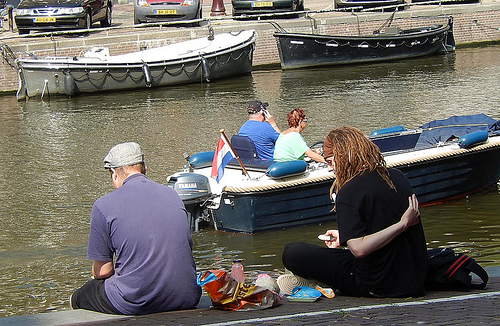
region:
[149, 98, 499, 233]
blue boat floating in the water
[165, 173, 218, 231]
outboard motor attached to boat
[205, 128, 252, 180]
flag hanging from flag pole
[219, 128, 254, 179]
flag pole attached to boat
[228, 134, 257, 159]
person leaning on blue backrest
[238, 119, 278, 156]
person wearing a bue shirt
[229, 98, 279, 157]
person is talking on the phone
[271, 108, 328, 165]
woman sitting inside the boat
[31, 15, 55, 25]
yellow license plate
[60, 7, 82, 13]
headlights on car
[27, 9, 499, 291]
a scene on the water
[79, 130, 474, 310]
these people are sitting near the water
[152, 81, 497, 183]
these people are boating on the water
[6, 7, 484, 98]
two boats parked along the dock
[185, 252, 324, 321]
a bunch of items on the platform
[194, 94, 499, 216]
this boat is blue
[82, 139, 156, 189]
this man is wearing a gray hat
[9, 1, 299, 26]
cars parked near the water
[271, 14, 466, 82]
a black boat docked on the water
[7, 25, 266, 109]
a white boat on the water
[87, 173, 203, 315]
The shirt is purple.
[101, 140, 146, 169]
The hat is gray.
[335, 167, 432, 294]
The shirt is black.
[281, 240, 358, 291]
The pants are black.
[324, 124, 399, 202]
The hair is in dreadlocks.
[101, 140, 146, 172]
The hat is a cabbie style hat.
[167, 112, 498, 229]
The side of the boat is blue.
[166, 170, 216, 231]
The boat has a motor attached.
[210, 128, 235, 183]
The flag has red, white, and blue bars.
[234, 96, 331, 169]
Two people are sitting in the boat.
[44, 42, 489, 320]
scene is at the sea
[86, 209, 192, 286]
the shirt is dull blue in color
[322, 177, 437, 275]
the lady is in a black outfit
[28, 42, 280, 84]
the boat is grey in color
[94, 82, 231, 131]
the water is colorles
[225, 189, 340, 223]
the boat is blue in color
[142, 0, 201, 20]
the car is silver in color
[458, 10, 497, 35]
the wall is red bricked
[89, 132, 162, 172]
the cape is colorles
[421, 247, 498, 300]
the bag is black with red stripes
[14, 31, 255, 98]
gray boat with white insides and assorted items hanging over its sides.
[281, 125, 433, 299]
woman with long brown hair, brown head band, black clothing and holding something in her right hand while her left hand is extended behind her back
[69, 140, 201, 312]
man sitting with purple shirt, black pants and white hat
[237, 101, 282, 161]
man talking on cell phone in a boat with blue tee shirt and brown hat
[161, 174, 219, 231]
blue boat motor with TAHARA on it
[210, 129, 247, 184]
red, white and blue striped flag on a boat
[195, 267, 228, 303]
small orange pail with blue handle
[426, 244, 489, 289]
black bag with handle and double orange stripe and zipper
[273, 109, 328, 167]
woman sitting in boat with light green shirt, glasses and orangish hair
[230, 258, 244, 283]
plastic clear drinking bottle with pink liquid in it and black lid